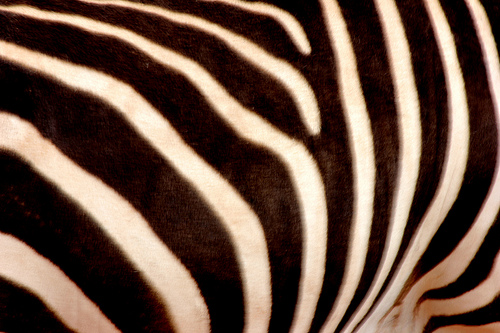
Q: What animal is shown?
A: A zebra.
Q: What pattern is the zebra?
A: Striped.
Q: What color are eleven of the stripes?
A: Black.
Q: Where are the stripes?
A: On the body.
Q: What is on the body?
A: Fur.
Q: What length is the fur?
A: Short.